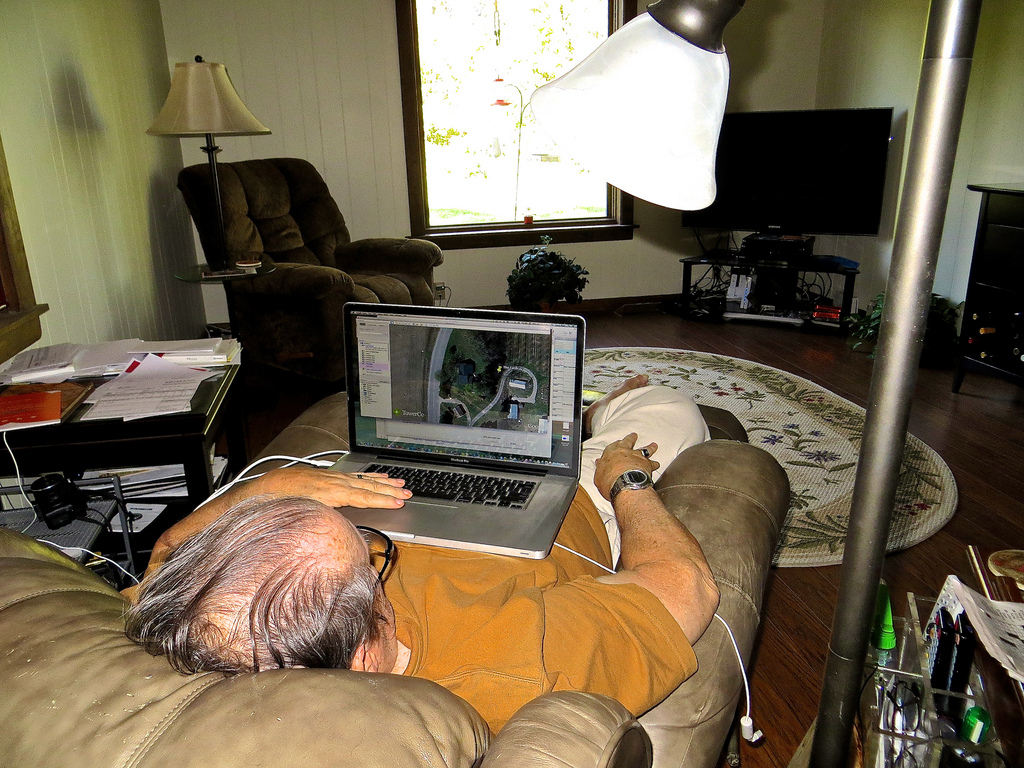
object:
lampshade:
[145, 56, 273, 139]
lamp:
[147, 56, 275, 272]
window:
[395, 0, 636, 250]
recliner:
[178, 158, 444, 382]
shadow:
[35, 43, 152, 340]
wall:
[0, 0, 402, 345]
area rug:
[580, 347, 960, 568]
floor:
[575, 310, 1022, 763]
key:
[485, 501, 498, 506]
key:
[433, 483, 446, 489]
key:
[458, 484, 471, 490]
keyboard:
[362, 464, 535, 510]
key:
[410, 480, 424, 487]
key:
[484, 484, 495, 488]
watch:
[610, 469, 656, 501]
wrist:
[600, 471, 669, 502]